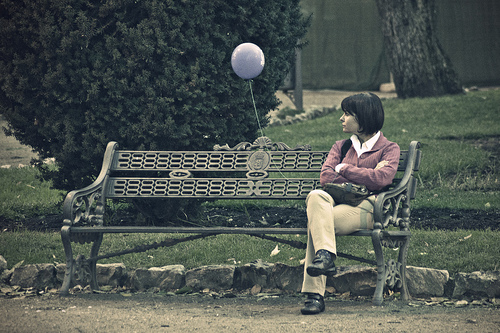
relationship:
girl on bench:
[306, 84, 383, 296] [75, 133, 374, 248]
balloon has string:
[223, 31, 270, 89] [246, 83, 276, 150]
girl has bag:
[306, 84, 383, 296] [321, 170, 371, 217]